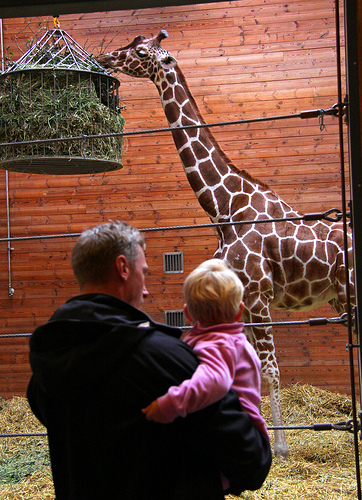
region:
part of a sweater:
[99, 417, 151, 481]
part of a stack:
[297, 432, 323, 462]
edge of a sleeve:
[150, 396, 185, 459]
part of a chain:
[314, 406, 342, 444]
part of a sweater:
[235, 385, 266, 424]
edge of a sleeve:
[137, 391, 176, 420]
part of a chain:
[294, 411, 326, 436]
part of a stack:
[292, 447, 321, 466]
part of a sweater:
[235, 370, 257, 395]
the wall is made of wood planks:
[0, 4, 357, 395]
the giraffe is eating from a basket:
[1, 25, 180, 175]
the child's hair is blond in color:
[183, 256, 244, 328]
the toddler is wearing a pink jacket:
[153, 323, 264, 433]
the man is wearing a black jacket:
[23, 294, 272, 495]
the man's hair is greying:
[73, 222, 146, 290]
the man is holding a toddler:
[30, 221, 269, 496]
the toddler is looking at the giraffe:
[158, 259, 270, 434]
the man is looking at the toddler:
[69, 220, 152, 316]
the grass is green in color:
[3, 46, 122, 164]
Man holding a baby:
[54, 217, 349, 471]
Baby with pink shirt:
[169, 307, 269, 404]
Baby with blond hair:
[180, 257, 254, 319]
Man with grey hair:
[71, 214, 150, 292]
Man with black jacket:
[35, 306, 191, 425]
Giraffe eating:
[84, 28, 197, 105]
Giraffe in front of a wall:
[105, 31, 325, 245]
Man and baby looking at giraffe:
[60, 199, 297, 392]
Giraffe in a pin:
[195, 138, 311, 362]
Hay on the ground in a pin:
[282, 387, 333, 493]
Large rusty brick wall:
[232, 33, 293, 92]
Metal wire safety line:
[269, 314, 344, 330]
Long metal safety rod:
[341, 197, 361, 441]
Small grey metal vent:
[159, 250, 185, 274]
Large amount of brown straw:
[300, 462, 339, 491]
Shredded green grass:
[4, 78, 115, 154]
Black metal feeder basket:
[29, 37, 79, 70]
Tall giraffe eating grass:
[107, 27, 214, 114]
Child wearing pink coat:
[167, 260, 262, 422]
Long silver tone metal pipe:
[2, 170, 18, 300]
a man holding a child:
[33, 196, 326, 497]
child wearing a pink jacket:
[121, 260, 318, 455]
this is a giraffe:
[91, 22, 345, 456]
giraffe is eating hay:
[2, 18, 224, 193]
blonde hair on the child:
[172, 260, 255, 315]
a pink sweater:
[144, 328, 269, 424]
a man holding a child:
[10, 214, 296, 496]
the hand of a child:
[136, 392, 178, 434]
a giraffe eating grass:
[45, 26, 207, 100]